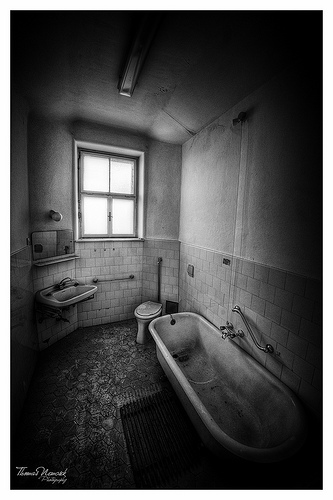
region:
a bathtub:
[173, 315, 231, 445]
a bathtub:
[184, 342, 233, 495]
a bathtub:
[195, 333, 228, 447]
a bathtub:
[160, 351, 222, 457]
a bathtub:
[217, 324, 252, 464]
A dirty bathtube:
[159, 334, 253, 409]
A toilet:
[131, 299, 160, 323]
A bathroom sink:
[41, 279, 100, 302]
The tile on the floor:
[52, 367, 109, 408]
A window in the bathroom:
[86, 172, 139, 224]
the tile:
[200, 259, 258, 307]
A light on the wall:
[45, 206, 72, 225]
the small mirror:
[38, 238, 70, 254]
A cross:
[104, 209, 117, 221]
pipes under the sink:
[44, 309, 83, 329]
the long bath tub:
[149, 310, 303, 451]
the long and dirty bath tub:
[147, 310, 302, 462]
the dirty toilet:
[135, 298, 158, 343]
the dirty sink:
[39, 275, 98, 305]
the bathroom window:
[71, 140, 147, 240]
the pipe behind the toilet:
[154, 256, 163, 305]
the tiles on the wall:
[196, 260, 224, 313]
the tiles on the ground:
[69, 337, 138, 379]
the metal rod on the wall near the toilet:
[92, 275, 137, 282]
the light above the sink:
[48, 208, 62, 221]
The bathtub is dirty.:
[149, 307, 256, 441]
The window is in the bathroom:
[63, 152, 147, 243]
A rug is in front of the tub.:
[119, 390, 187, 464]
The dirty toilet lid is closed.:
[108, 273, 166, 326]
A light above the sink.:
[43, 201, 69, 227]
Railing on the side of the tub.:
[220, 290, 288, 369]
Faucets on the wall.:
[207, 307, 243, 346]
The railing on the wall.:
[86, 264, 151, 293]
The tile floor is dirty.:
[65, 339, 156, 391]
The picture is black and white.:
[61, 187, 299, 441]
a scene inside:
[19, 26, 331, 497]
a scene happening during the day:
[14, 11, 326, 487]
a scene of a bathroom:
[24, 87, 312, 466]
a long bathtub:
[147, 301, 322, 498]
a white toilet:
[127, 292, 164, 352]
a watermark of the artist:
[0, 459, 87, 489]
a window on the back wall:
[73, 142, 159, 249]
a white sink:
[37, 260, 105, 333]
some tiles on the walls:
[36, 233, 330, 367]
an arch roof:
[1, 5, 227, 186]